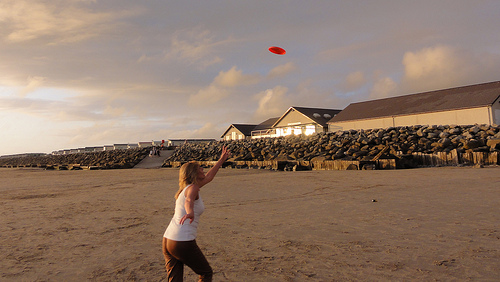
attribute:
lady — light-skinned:
[151, 147, 228, 280]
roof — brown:
[330, 83, 497, 120]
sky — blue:
[7, 1, 498, 154]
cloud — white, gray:
[183, 66, 299, 113]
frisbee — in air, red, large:
[270, 48, 289, 58]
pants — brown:
[160, 240, 213, 280]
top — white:
[163, 185, 206, 235]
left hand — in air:
[219, 146, 235, 165]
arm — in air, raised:
[204, 145, 230, 184]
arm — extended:
[182, 180, 199, 222]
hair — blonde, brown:
[176, 158, 200, 195]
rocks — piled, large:
[1, 123, 492, 170]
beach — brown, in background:
[4, 170, 496, 275]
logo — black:
[271, 46, 278, 49]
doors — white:
[220, 132, 243, 142]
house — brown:
[223, 122, 257, 141]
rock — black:
[371, 199, 378, 205]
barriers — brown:
[182, 151, 494, 167]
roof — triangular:
[237, 122, 263, 133]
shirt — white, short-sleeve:
[167, 185, 204, 240]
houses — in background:
[223, 107, 343, 139]